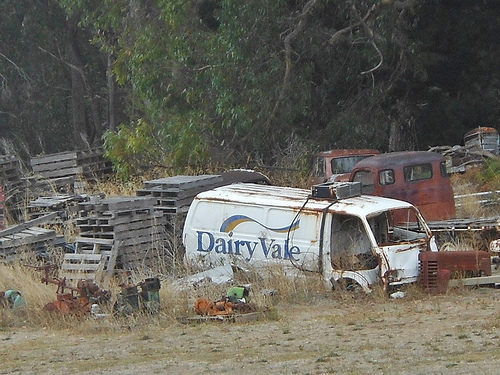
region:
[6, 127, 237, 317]
stacks of pallets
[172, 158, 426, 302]
white van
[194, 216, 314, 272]
Dairy Vale written on van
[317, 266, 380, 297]
van is missing tire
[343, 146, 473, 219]
red truck by van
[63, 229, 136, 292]
pallets against stack of pallets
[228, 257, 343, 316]
tall grass in front of van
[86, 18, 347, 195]
trees behind the pallets and vehicles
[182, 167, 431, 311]
white truck in grass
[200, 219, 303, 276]
blue and orange logo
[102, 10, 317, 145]
green tree behind truck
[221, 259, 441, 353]
grass is dark brown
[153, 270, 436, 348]
grass is thin and wispy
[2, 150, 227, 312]
grey pallets behind truck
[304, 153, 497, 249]
red truck behind white truck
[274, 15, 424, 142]
brown branches on tree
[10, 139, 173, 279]
stack of wooden pallets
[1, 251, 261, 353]
various equipment on ground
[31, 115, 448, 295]
trucks in the field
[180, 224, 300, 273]
logo on the truck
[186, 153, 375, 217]
the truck is rusted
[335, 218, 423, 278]
front cab of van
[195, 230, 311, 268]
truck for dairy vale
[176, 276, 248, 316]
tools in the field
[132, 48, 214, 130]
trees in the field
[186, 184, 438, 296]
A broken down van at the scrap yard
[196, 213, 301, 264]
A Dairy Vale logo on the old van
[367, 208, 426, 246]
The van is missing a windshield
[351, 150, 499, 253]
An old truck next to the old van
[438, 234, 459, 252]
A rear tire on the old truck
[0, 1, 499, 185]
Trees growing near the old vehicles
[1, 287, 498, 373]
Grass around the scrap yard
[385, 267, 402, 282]
A broken headlight on the old van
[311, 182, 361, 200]
A box on top of the old van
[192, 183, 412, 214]
The roof of the old van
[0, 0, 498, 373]
A broken car dump site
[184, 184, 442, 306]
The white scrapped truck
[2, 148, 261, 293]
The heaped gray parts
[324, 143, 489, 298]
The old brown trucks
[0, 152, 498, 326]
The overgrown grass in a dumpsite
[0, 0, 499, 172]
The thick background vegetation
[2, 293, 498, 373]
An open front passage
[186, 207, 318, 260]
The blue printed brand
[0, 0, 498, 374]
A messy dumping area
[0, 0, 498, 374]
A neglected car garage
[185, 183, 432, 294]
van is color white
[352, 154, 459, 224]
van is color red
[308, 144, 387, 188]
van is color red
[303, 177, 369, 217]
box is on top of the van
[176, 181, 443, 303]
van is on ground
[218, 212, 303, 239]
van has a logo on it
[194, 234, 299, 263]
van has writing on it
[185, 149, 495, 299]
van is behind the white van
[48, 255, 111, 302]
A old wooden pallet.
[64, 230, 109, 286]
A old wooden pallet.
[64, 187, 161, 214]
A old wooden pallet.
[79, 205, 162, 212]
A old wooden pallet.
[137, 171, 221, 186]
A old wooden pallet.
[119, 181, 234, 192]
A old wooden pallet.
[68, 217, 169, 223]
A old wooden pallet.